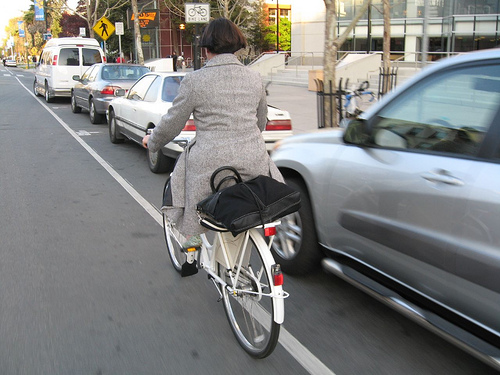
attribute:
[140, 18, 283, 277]
person — dark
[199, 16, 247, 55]
hair — short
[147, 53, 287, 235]
jacket — gray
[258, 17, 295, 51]
leaves — green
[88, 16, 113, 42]
sign — yellow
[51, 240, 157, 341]
road — black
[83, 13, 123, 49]
sign — black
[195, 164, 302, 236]
bag — black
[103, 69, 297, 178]
car — white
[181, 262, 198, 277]
shoe — black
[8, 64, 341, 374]
line — white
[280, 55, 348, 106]
stairs — gray, concrete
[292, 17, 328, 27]
roof — white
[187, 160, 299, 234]
bag — black